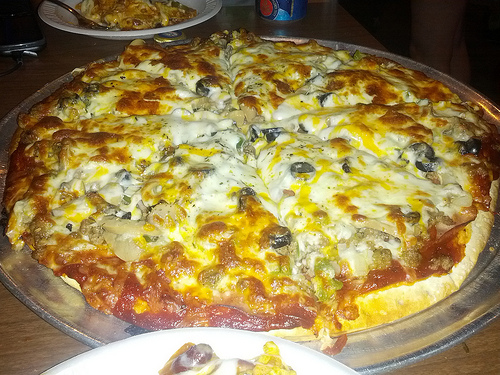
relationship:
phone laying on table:
[1, 2, 45, 58] [309, 3, 385, 43]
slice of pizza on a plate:
[78, 1, 190, 30] [37, 1, 226, 39]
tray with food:
[1, 35, 497, 375] [17, 44, 497, 339]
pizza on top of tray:
[9, 38, 497, 330] [1, 35, 497, 375]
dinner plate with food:
[37, 1, 226, 39] [78, 1, 190, 30]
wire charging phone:
[2, 51, 24, 79] [1, 2, 45, 58]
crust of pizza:
[74, 271, 227, 339] [9, 38, 497, 330]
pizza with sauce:
[9, 38, 497, 330] [367, 230, 464, 286]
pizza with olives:
[9, 38, 497, 330] [248, 122, 293, 144]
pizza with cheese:
[9, 38, 497, 330] [85, 67, 182, 162]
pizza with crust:
[9, 38, 497, 330] [74, 271, 227, 339]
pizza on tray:
[9, 38, 497, 330] [1, 35, 497, 375]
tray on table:
[1, 35, 497, 375] [309, 3, 385, 43]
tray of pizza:
[1, 35, 497, 375] [9, 38, 497, 330]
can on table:
[256, 0, 306, 23] [309, 3, 385, 43]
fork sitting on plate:
[46, 0, 107, 32] [37, 1, 226, 39]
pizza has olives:
[9, 38, 497, 330] [248, 122, 293, 144]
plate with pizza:
[37, 1, 226, 39] [78, 1, 190, 30]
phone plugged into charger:
[1, 2, 45, 58] [2, 51, 24, 79]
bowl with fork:
[37, 1, 226, 39] [46, 0, 107, 32]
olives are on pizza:
[248, 122, 293, 144] [9, 38, 497, 330]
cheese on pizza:
[85, 67, 182, 162] [9, 38, 497, 330]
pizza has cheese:
[9, 38, 497, 330] [85, 67, 182, 162]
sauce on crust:
[367, 230, 464, 286] [74, 271, 227, 339]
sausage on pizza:
[427, 201, 478, 245] [9, 38, 497, 330]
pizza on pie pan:
[9, 38, 497, 330] [1, 35, 497, 375]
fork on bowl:
[46, 0, 107, 32] [37, 1, 226, 39]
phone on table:
[1, 2, 45, 58] [309, 3, 385, 43]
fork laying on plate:
[46, 0, 107, 32] [37, 1, 226, 39]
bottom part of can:
[257, 1, 308, 22] [256, 0, 306, 23]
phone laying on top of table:
[1, 2, 45, 58] [309, 3, 385, 43]